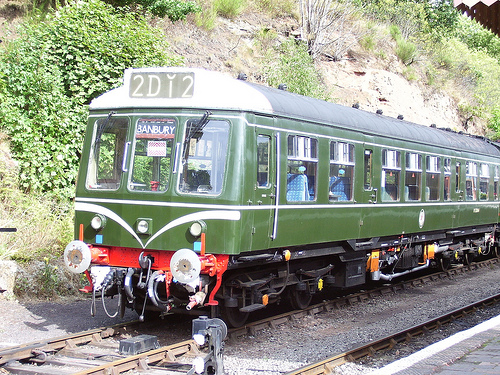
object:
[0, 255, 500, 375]
rail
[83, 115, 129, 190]
train window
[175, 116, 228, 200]
window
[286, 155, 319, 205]
train window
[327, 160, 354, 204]
train window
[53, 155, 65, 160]
leaves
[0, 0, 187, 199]
tree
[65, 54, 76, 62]
leaves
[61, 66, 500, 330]
train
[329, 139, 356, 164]
window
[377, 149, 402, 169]
window